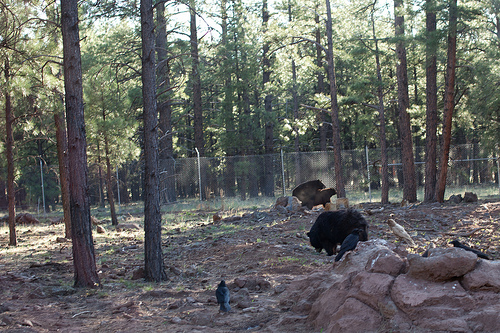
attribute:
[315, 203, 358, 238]
bear — black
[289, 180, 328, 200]
bear — brown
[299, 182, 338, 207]
bear — brown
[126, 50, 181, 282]
tree — tall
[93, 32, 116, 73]
leaf — green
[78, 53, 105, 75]
leaf — green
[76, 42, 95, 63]
leaf — green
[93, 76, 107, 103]
leaf — green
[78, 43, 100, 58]
leaf — green